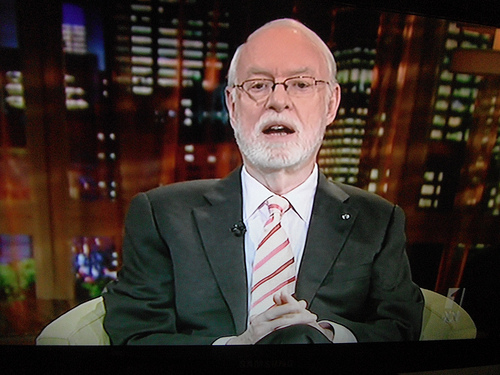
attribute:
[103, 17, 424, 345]
man — speaking, older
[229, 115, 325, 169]
beard — grey, white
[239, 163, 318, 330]
collared shirt — white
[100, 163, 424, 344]
suit jacket — dark grey, black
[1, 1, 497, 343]
background — brown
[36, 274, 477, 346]
chair — white, curved, tan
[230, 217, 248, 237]
microphone — small, black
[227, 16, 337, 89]
hair — grey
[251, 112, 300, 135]
mustache — grey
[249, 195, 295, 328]
tie — white pink, red, white, striped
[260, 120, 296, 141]
mouth — open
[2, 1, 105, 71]
sky — deep blue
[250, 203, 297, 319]
stripes — red, slanted, pink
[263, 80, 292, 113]
nose — white